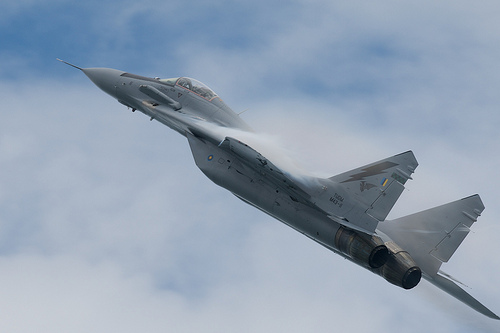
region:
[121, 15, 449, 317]
A jet in the sky.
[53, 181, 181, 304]
The sky is cloudy.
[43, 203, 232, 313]
The clouds are white.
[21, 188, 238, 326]
The sky is blue.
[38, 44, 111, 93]
The jet has a pointed nose.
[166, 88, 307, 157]
Smoke coming from the plane.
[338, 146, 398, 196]
A lighting bolt on the tail.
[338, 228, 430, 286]
The engine of the plane.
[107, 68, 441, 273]
The plane is gray.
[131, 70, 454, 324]
The plane is going upward.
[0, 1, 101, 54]
blue sky with whispy clouds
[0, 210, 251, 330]
white clouds in the sky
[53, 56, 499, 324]
plane flying in a cloudy sky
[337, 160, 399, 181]
lightning bolt painted on a plane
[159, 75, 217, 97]
glass over cockpit of a plane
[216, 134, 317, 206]
wing on the side of a plane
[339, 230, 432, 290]
engines located on back of a plane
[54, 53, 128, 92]
nose of a plane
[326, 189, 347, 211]
writing to identify plane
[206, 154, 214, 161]
emblem painted on a plane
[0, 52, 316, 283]
jet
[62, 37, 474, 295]
military jet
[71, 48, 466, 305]
gray military jet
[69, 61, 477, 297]
gray military jet flying in air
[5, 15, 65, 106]
white clouds against blue sky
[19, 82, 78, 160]
white clouds against blue sky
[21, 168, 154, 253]
white clouds against blue sky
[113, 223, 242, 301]
white clouds against blue sky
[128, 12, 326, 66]
white clouds against blue sky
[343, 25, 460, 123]
white clouds against blue sky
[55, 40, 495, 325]
fighter jet climbing through the air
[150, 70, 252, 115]
cockpit of fighter jet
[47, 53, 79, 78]
pointed nose of fighter jet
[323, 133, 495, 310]
wings on back of fighter jet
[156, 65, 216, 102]
window on fighter jet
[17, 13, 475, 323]
sky fighter jet is flying through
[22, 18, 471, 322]
wispy clouds in sky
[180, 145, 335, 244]
underside of the fighter jet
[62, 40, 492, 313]
gray fighter jet flying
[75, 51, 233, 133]
front of fighter jet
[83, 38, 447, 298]
gray military jet in flight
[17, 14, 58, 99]
white clouds in blue sky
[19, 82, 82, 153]
white clouds in blue sky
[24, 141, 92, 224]
white clouds in blue sky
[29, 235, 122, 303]
white clouds in blue sky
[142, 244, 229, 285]
white clouds in blue sky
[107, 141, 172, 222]
white clouds in blue sky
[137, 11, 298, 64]
white clouds in blue sky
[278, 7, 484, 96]
white clouds in blue sky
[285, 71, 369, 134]
white clouds in blue sky